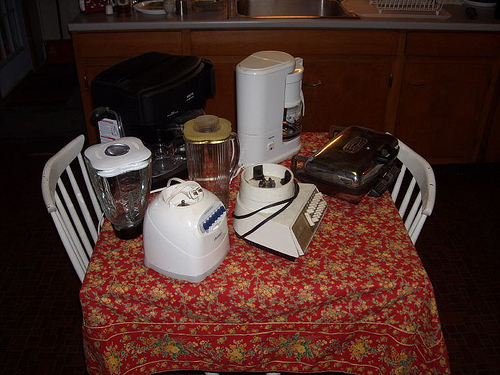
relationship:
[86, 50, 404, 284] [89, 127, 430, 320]
appliances on table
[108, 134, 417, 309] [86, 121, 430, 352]
cloth on table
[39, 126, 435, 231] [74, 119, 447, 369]
chair on table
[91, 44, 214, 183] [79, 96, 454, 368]
espresso machine on table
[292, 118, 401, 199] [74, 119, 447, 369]
waffle maker on table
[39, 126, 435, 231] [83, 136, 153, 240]
chair with appliances